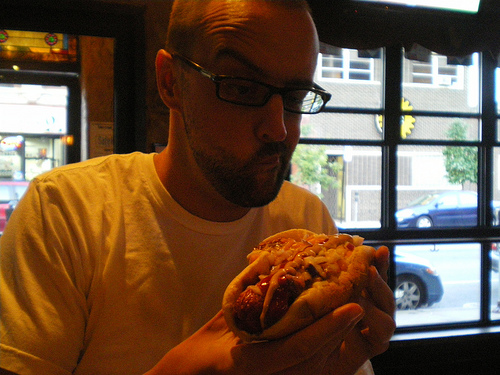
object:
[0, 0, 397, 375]
man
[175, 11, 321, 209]
face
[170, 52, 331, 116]
glasses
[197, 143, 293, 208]
beard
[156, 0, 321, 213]
head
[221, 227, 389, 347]
hot dog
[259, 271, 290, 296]
ketchup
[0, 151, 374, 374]
shirt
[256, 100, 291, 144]
nose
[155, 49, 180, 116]
ear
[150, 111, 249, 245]
neck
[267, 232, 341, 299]
cheese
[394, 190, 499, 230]
car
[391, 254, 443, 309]
car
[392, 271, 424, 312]
front wheel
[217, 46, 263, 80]
eyebrow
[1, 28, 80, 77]
window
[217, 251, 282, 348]
roll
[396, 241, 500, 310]
road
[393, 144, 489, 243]
window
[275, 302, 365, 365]
finger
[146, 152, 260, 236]
collar